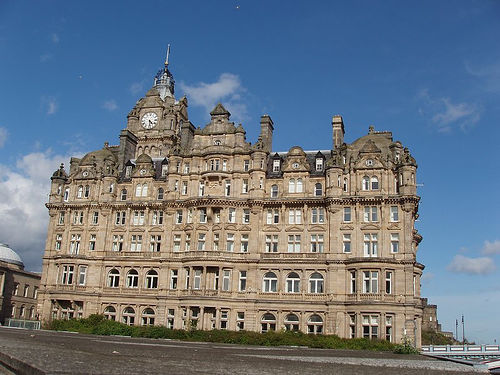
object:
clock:
[140, 112, 158, 130]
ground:
[34, 328, 159, 371]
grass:
[105, 316, 223, 340]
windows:
[361, 270, 379, 295]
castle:
[34, 41, 425, 351]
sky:
[396, 89, 498, 312]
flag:
[163, 43, 172, 64]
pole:
[164, 43, 170, 69]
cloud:
[446, 252, 495, 278]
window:
[309, 233, 325, 254]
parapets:
[118, 128, 139, 175]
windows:
[144, 269, 160, 290]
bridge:
[421, 344, 500, 360]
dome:
[0, 245, 24, 271]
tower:
[125, 42, 188, 139]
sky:
[188, 83, 428, 126]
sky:
[231, 11, 442, 85]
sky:
[12, 21, 140, 136]